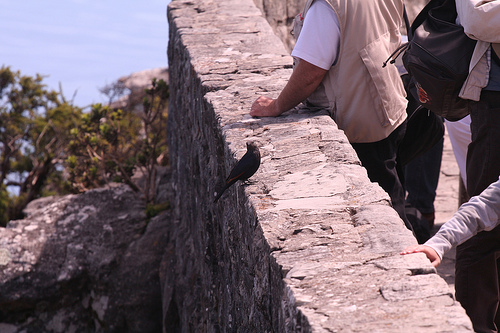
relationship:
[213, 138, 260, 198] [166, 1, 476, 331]
bird on rock wall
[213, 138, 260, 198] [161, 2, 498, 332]
bird on a rock wall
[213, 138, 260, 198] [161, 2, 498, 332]
bird on wall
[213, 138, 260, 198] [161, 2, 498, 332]
bird perched on wall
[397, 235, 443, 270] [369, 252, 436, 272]
hand on rocks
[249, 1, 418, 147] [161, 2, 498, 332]
man next to wall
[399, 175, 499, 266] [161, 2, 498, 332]
person next to wall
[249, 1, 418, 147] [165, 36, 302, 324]
man leaning against wall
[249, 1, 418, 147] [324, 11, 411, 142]
man wearing tan vest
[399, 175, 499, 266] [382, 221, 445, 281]
person touching wall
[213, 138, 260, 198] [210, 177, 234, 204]
bird has tail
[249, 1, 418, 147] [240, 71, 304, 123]
man has hand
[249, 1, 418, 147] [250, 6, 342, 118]
man has arm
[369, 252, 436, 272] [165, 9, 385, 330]
rocks on wall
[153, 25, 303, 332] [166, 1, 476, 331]
rocks on rock wall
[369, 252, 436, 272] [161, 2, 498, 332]
rocks on wall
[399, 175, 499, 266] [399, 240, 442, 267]
person has hand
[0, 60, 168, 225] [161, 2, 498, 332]
trees near wall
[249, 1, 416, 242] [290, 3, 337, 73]
man wearing white shirt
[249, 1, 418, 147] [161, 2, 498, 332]
man standing by wall